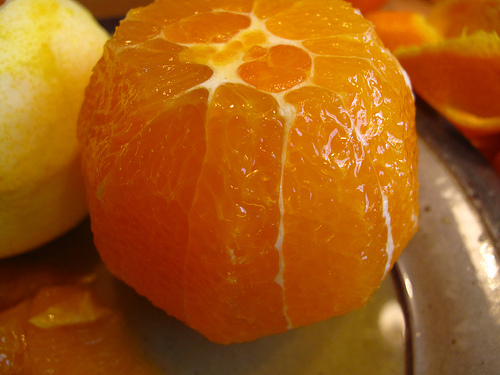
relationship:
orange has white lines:
[80, 2, 440, 337] [92, 0, 418, 332]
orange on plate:
[80, 2, 440, 337] [133, 123, 490, 373]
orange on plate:
[80, 2, 440, 337] [357, 307, 490, 369]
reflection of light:
[434, 176, 496, 311] [449, 205, 497, 292]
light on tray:
[449, 205, 497, 292] [414, 193, 498, 304]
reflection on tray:
[434, 176, 496, 311] [414, 193, 498, 304]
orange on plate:
[80, 2, 440, 337] [9, 14, 494, 372]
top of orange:
[126, 26, 348, 104] [80, 2, 440, 337]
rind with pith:
[368, 12, 498, 140] [398, 31, 497, 52]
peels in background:
[386, 2, 498, 154] [78, 2, 497, 157]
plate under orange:
[0, 99, 500, 370] [80, 2, 440, 337]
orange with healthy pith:
[80, 2, 440, 337] [199, 15, 290, 78]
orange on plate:
[80, 2, 440, 337] [426, 284, 472, 338]